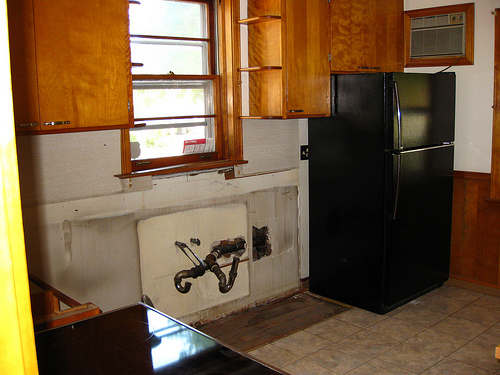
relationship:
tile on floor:
[425, 290, 469, 317] [218, 313, 500, 374]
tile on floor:
[374, 338, 447, 369] [218, 313, 500, 374]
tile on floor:
[306, 343, 375, 370] [218, 313, 500, 374]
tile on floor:
[296, 307, 342, 336] [218, 313, 500, 374]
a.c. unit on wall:
[408, 13, 468, 60] [403, 1, 496, 291]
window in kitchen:
[126, 2, 229, 173] [10, 5, 496, 372]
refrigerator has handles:
[306, 69, 459, 313] [386, 80, 402, 222]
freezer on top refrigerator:
[380, 74, 461, 149] [306, 69, 459, 313]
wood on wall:
[451, 176, 497, 290] [403, 1, 496, 291]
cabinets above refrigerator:
[239, 2, 407, 117] [306, 69, 459, 313]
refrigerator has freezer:
[306, 69, 459, 313] [380, 74, 461, 149]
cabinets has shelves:
[239, 2, 407, 117] [231, 0, 284, 117]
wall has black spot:
[17, 115, 306, 328] [72, 206, 82, 215]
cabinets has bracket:
[239, 2, 407, 117] [123, 101, 135, 116]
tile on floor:
[275, 328, 329, 357] [218, 313, 500, 374]